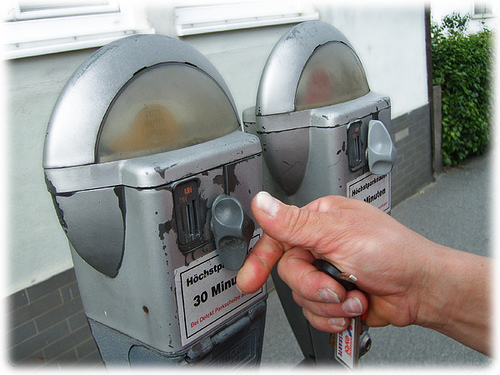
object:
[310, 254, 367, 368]
keys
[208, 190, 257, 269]
knob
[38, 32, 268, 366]
parking meter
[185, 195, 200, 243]
coin slot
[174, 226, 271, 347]
meter instructions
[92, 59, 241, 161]
meter window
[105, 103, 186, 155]
flag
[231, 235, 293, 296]
finger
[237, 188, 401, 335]
hand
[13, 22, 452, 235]
building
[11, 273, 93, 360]
foundation